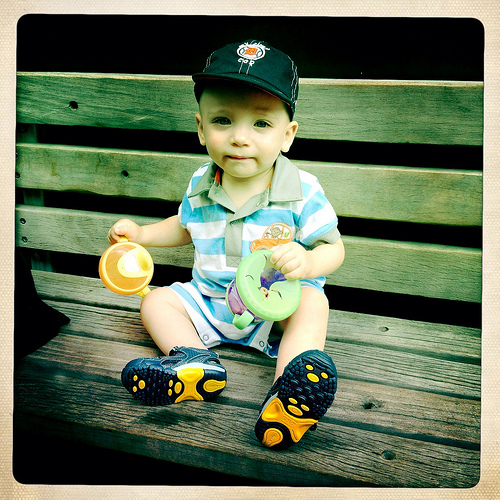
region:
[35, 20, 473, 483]
Little boy sitting on a wooden bench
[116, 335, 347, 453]
Little kid shoes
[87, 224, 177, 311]
Orange sippy cup for little ones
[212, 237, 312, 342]
Green and purple snack cup filled with cheerios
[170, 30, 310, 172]
Little boy with a black baseball cap on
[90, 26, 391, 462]
Little boy wearing a blue and white striped onesie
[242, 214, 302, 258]
Car design sewed onto the boy's clothes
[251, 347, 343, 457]
Black and yellow tread on the bottom of the boys shoe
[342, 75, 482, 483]
Wooden bench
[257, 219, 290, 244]
Monkey driving the car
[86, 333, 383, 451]
Blue and yellow baby shoes.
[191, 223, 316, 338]
Green and purple sippy cup.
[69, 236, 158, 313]
Yellow and clear sippy cup.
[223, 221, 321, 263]
Orange car logo on outfit.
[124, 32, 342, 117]
Blue and orange baseball cap.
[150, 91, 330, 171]
Face of a baby.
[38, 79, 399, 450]
Baby sitting on a bench.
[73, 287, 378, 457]
Legs and shoes of a baby.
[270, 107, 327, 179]
Ear on a baby.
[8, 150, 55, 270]
Screws in a bench.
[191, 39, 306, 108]
A baseball cap.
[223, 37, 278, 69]
Logo on a baseball cap.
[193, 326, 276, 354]
Snaps on a childs outfit.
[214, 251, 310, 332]
A child's hand holding a cup.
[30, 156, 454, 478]
A wooden bench.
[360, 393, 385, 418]
A nail in a bench.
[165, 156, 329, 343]
A blue and white striped jumpsuit.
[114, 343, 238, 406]
Tennis shoe.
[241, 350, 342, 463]
Yellow and black soles of a tennis shoes.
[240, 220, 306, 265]
An emblem on a child's jumpsuit.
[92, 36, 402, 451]
baby boy with toys in each hand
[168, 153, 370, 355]
blue and white striped baby's onesie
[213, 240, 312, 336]
green and purple plastic cup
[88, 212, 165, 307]
orange and yellow plastic cup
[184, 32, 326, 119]
black baseball cap with white and orange logo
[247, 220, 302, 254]
orange embroidered car patch with a brown monkey driver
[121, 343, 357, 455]
black sandals with black and yellow rubber bottoms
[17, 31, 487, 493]
wooden bench with a baby sitting on it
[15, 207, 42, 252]
two metal rivets in a wooden plank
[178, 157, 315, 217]
tan collar of a shirt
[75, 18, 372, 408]
young boy sitting on a bench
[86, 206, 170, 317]
The kid is holding a juice cup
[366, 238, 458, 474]
An old wooden bench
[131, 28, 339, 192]
The kid is wearing a hat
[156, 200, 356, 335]
Kid wearing a blue and white striped shirt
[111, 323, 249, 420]
Yellow and Black shoes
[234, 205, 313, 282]
Cartoon patch on shirt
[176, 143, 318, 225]
A kids collared shirt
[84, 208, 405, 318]
The kid is using both hands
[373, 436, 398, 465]
knot in the wood of the bench